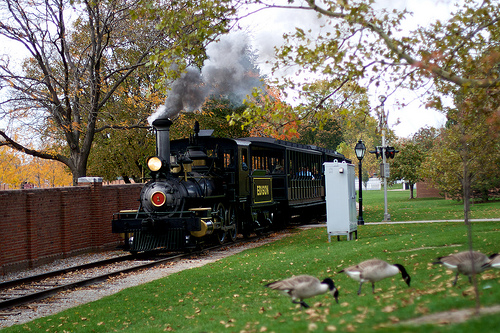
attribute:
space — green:
[258, 229, 450, 272]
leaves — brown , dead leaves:
[372, 282, 444, 310]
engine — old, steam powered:
[129, 122, 276, 252]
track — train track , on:
[0, 239, 189, 312]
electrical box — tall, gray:
[323, 158, 356, 241]